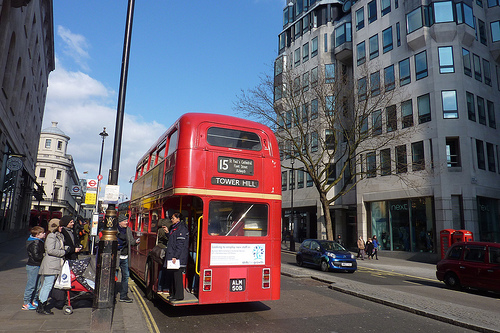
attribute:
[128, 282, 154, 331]
line — yellow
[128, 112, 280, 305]
double decker — red, large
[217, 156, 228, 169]
number — 15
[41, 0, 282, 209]
sky — blue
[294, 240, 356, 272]
sports car — blue, small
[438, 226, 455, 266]
box — red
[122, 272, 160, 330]
line — double, yellow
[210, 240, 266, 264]
sign — white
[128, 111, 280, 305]
bus — red, double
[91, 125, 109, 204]
street light — metal, pointy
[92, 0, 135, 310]
street lamp — black, gold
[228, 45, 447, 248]
tree — bare, big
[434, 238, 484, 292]
car — red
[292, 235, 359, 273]
car — blue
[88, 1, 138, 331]
post — black, metal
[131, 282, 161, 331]
line — yellow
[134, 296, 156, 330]
line —  yellow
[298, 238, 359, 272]
car — blue, driving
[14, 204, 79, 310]
people — group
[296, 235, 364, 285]
car — small, blue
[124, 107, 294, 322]
bus — red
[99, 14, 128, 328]
post — black, metal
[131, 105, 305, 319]
bus — red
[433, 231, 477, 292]
telephone booth — red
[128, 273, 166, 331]
line — yellow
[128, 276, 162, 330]
line — yellow